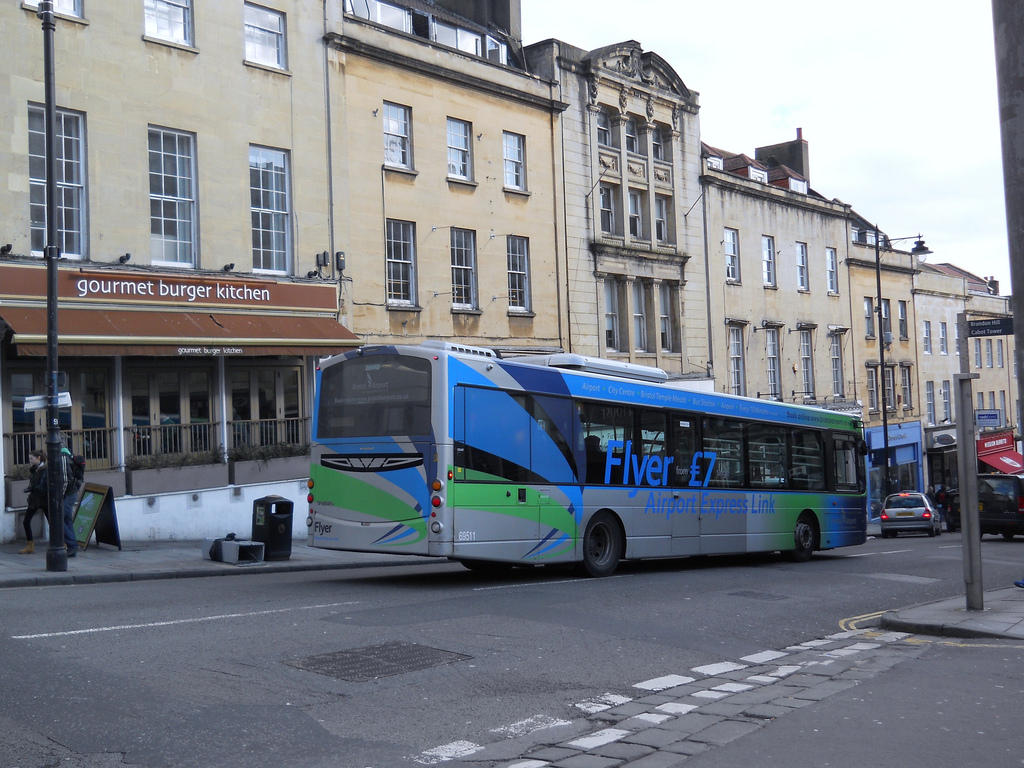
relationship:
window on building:
[337, 191, 454, 306] [321, 46, 576, 440]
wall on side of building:
[297, 44, 410, 358] [12, 16, 1002, 427]